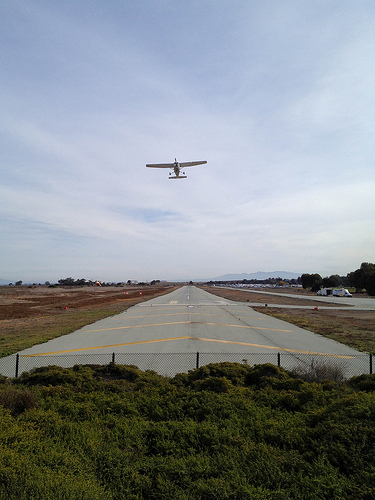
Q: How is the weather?
A: It is cloudy.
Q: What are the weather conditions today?
A: It is cloudy.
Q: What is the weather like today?
A: It is cloudy.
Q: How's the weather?
A: It is cloudy.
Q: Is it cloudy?
A: Yes, it is cloudy.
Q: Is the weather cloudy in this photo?
A: Yes, it is cloudy.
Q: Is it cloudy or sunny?
A: It is cloudy.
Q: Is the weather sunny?
A: No, it is cloudy.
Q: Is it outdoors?
A: Yes, it is outdoors.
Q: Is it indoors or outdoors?
A: It is outdoors.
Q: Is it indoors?
A: No, it is outdoors.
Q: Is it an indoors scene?
A: No, it is outdoors.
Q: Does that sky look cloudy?
A: Yes, the sky is cloudy.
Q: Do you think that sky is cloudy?
A: Yes, the sky is cloudy.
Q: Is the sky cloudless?
A: No, the sky is cloudy.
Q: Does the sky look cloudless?
A: No, the sky is cloudy.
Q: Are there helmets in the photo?
A: No, there are no helmets.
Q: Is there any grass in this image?
A: Yes, there is grass.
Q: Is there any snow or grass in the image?
A: Yes, there is grass.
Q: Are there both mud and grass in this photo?
A: No, there is grass but no mud.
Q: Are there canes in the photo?
A: No, there are no canes.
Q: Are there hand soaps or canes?
A: No, there are no canes or hand soaps.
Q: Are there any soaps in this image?
A: No, there are no soaps.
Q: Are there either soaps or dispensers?
A: No, there are no soaps or dispensers.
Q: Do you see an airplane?
A: Yes, there is an airplane.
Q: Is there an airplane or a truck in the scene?
A: Yes, there is an airplane.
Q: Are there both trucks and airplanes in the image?
A: Yes, there are both an airplane and a truck.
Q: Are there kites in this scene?
A: No, there are no kites.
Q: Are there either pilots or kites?
A: No, there are no kites or pilots.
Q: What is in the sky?
A: The plane is in the sky.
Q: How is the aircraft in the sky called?
A: The aircraft is an airplane.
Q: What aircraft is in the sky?
A: The aircraft is an airplane.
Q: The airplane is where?
A: The airplane is in the sky.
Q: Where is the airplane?
A: The airplane is in the sky.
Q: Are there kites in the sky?
A: No, there is an airplane in the sky.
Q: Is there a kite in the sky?
A: No, there is an airplane in the sky.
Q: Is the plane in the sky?
A: Yes, the plane is in the sky.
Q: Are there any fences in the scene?
A: Yes, there is a fence.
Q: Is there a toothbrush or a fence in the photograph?
A: Yes, there is a fence.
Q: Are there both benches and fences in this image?
A: No, there is a fence but no benches.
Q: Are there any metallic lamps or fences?
A: Yes, there is a metal fence.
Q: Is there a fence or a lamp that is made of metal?
A: Yes, the fence is made of metal.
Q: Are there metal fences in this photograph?
A: Yes, there is a fence that is made of metal.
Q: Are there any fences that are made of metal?
A: Yes, there is a fence that is made of metal.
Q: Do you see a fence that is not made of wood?
A: Yes, there is a fence that is made of metal.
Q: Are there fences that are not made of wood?
A: Yes, there is a fence that is made of metal.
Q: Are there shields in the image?
A: No, there are no shields.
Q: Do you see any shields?
A: No, there are no shields.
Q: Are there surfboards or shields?
A: No, there are no shields or surfboards.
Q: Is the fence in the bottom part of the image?
A: Yes, the fence is in the bottom of the image.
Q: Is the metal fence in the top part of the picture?
A: No, the fence is in the bottom of the image.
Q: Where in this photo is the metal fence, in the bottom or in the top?
A: The fence is in the bottom of the image.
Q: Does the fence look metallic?
A: Yes, the fence is metallic.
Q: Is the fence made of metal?
A: Yes, the fence is made of metal.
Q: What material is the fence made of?
A: The fence is made of metal.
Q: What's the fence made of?
A: The fence is made of metal.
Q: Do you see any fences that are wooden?
A: No, there is a fence but it is metallic.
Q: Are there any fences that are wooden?
A: No, there is a fence but it is metallic.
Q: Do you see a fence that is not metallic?
A: No, there is a fence but it is metallic.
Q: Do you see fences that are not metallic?
A: No, there is a fence but it is metallic.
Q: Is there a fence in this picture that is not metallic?
A: No, there is a fence but it is metallic.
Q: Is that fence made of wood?
A: No, the fence is made of metal.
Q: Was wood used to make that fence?
A: No, the fence is made of metal.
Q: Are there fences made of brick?
A: No, there is a fence but it is made of metal.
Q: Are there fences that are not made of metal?
A: No, there is a fence but it is made of metal.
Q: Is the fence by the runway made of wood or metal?
A: The fence is made of metal.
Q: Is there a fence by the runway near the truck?
A: Yes, there is a fence by the runway.